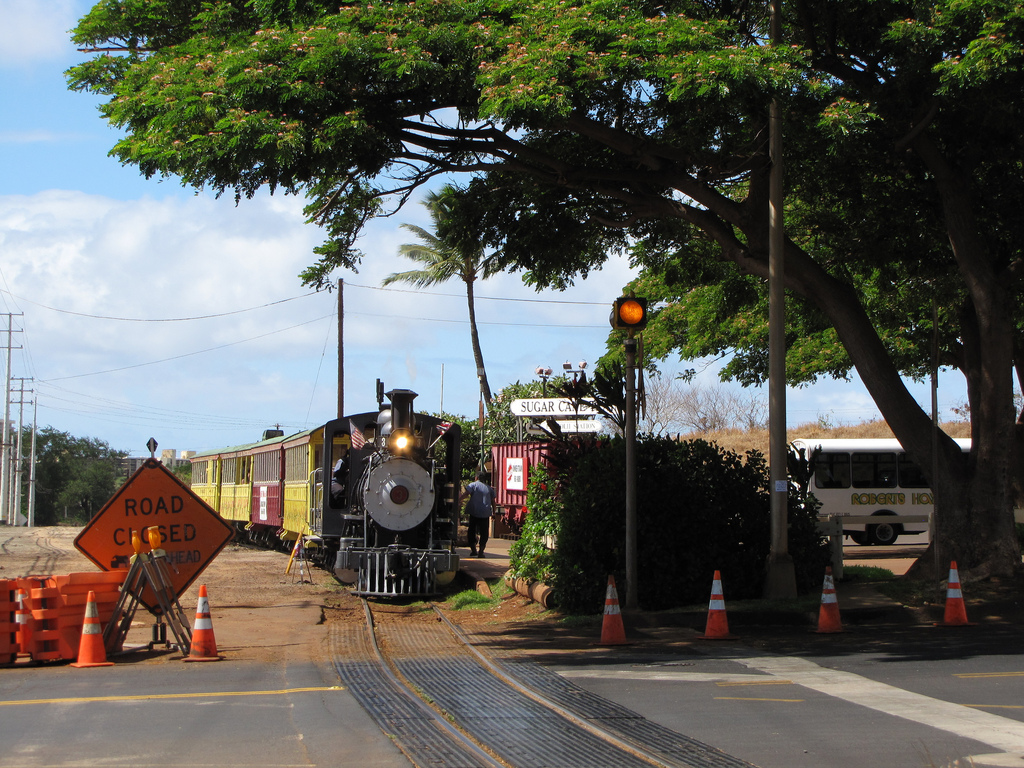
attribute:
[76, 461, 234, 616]
road sign — orange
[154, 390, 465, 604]
train — crossing, yellow, black, traveling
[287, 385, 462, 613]
car — engine car, yellow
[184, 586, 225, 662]
street cone — orange, white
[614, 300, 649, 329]
light — orange, red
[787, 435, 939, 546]
bus — white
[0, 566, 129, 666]
barricade — orange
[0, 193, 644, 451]
clouds — white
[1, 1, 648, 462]
sky — blue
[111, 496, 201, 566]
lettering — black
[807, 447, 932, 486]
windows — black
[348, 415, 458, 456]
flags — american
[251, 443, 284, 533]
car — red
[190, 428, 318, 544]
cars — yellow, three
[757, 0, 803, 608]
pole — gray, tall